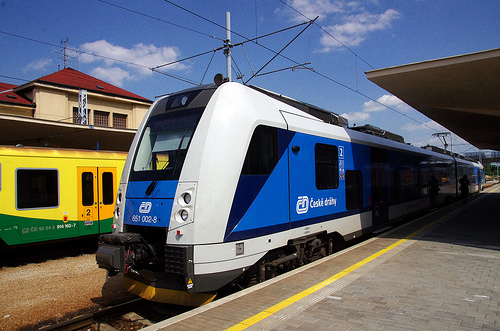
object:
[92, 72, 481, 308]
train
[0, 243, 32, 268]
wheels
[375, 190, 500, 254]
shadow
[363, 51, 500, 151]
overhang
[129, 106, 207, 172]
windshield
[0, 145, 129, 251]
passenger car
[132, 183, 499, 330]
platform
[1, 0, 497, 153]
sky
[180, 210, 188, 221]
headlight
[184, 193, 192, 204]
headlight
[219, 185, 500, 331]
line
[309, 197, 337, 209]
name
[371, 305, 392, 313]
bricks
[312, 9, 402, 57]
cloud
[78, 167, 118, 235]
door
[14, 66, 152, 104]
roof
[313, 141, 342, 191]
window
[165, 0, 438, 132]
wire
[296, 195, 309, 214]
logo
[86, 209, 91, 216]
number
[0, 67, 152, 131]
building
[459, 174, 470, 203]
person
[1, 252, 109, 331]
dirt